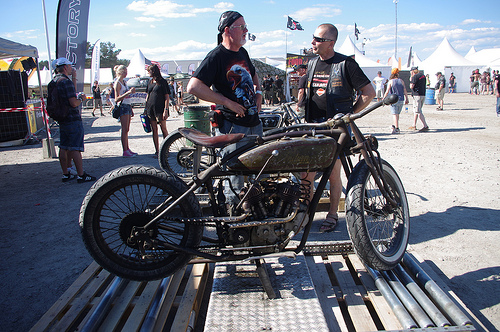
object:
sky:
[79, 3, 496, 50]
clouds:
[104, 1, 215, 34]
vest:
[304, 56, 353, 115]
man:
[184, 10, 266, 208]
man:
[297, 22, 376, 233]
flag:
[286, 15, 305, 30]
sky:
[414, 11, 497, 44]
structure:
[30, 244, 494, 332]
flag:
[353, 22, 361, 40]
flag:
[248, 32, 256, 41]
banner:
[55, 0, 88, 93]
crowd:
[21, 38, 494, 128]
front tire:
[343, 156, 410, 271]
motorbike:
[78, 93, 412, 300]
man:
[45, 57, 95, 183]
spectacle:
[311, 34, 337, 43]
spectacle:
[231, 24, 247, 29]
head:
[312, 22, 338, 54]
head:
[220, 10, 249, 46]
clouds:
[363, 11, 500, 36]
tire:
[76, 163, 205, 282]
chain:
[118, 210, 246, 252]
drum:
[184, 104, 211, 146]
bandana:
[217, 10, 244, 47]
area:
[7, 156, 490, 330]